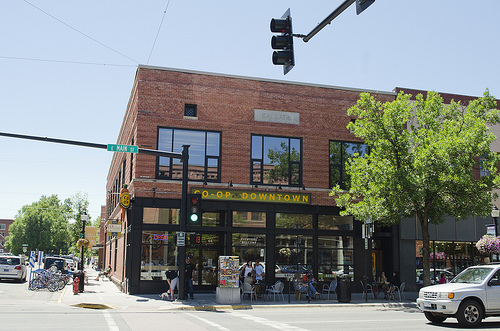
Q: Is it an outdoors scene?
A: Yes, it is outdoors.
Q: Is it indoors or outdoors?
A: It is outdoors.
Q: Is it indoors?
A: No, it is outdoors.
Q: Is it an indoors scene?
A: No, it is outdoors.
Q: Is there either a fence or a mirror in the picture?
A: No, there are no fences or mirrors.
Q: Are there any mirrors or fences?
A: No, there are no fences or mirrors.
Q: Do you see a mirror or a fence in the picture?
A: No, there are no fences or mirrors.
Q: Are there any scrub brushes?
A: No, there are no scrub brushes.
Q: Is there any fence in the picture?
A: No, there are no fences.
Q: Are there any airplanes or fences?
A: No, there are no fences or airplanes.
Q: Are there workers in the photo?
A: No, there are no workers.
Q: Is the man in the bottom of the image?
A: Yes, the man is in the bottom of the image.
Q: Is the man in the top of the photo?
A: No, the man is in the bottom of the image.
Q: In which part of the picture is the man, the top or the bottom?
A: The man is in the bottom of the image.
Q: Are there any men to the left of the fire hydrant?
A: No, the man is to the right of the fire hydrant.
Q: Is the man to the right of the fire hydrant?
A: Yes, the man is to the right of the fire hydrant.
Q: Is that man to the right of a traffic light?
A: No, the man is to the right of the fire hydrant.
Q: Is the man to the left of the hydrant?
A: No, the man is to the right of the hydrant.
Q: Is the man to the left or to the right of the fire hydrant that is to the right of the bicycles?
A: The man is to the right of the hydrant.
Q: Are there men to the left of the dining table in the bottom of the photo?
A: Yes, there is a man to the left of the dining table.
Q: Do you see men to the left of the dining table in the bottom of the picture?
A: Yes, there is a man to the left of the dining table.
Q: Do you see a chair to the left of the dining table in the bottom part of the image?
A: No, there is a man to the left of the dining table.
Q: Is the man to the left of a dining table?
A: Yes, the man is to the left of a dining table.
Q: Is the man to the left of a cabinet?
A: No, the man is to the left of a dining table.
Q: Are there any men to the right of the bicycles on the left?
A: Yes, there is a man to the right of the bicycles.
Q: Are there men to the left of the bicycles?
A: No, the man is to the right of the bicycles.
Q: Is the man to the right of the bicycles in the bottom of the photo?
A: Yes, the man is to the right of the bicycles.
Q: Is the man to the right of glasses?
A: No, the man is to the right of the bicycles.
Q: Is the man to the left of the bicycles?
A: No, the man is to the right of the bicycles.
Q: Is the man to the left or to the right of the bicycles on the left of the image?
A: The man is to the right of the bicycles.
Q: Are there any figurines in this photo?
A: No, there are no figurines.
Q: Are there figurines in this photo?
A: No, there are no figurines.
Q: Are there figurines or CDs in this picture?
A: No, there are no figurines or cds.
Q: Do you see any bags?
A: No, there are no bags.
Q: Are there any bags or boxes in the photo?
A: No, there are no bags or boxes.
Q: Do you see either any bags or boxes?
A: No, there are no bags or boxes.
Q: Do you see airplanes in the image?
A: No, there are no airplanes.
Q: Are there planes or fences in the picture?
A: No, there are no planes or fences.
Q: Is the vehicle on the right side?
A: Yes, the vehicle is on the right of the image.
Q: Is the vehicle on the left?
A: No, the vehicle is on the right of the image.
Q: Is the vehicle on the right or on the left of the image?
A: The vehicle is on the right of the image.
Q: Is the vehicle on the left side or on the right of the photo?
A: The vehicle is on the right of the image.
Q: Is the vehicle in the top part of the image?
A: No, the vehicle is in the bottom of the image.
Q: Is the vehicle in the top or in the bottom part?
A: The vehicle is in the bottom of the image.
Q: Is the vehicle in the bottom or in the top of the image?
A: The vehicle is in the bottom of the image.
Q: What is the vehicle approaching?
A: The vehicle is approaching the intersection.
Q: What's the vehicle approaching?
A: The vehicle is approaching the intersection.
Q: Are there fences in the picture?
A: No, there are no fences.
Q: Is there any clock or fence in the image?
A: No, there are no fences or clocks.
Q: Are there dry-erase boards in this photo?
A: No, there are no dry-erase boards.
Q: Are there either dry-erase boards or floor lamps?
A: No, there are no dry-erase boards or floor lamps.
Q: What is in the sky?
A: The clouds are in the sky.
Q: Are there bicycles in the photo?
A: Yes, there are bicycles.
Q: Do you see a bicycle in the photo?
A: Yes, there are bicycles.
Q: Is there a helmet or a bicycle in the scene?
A: Yes, there are bicycles.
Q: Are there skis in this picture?
A: No, there are no skis.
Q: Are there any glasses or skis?
A: No, there are no skis or glasses.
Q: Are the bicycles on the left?
A: Yes, the bicycles are on the left of the image.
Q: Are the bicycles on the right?
A: No, the bicycles are on the left of the image.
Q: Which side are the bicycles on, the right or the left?
A: The bicycles are on the left of the image.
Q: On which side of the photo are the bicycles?
A: The bicycles are on the left of the image.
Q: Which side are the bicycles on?
A: The bicycles are on the left of the image.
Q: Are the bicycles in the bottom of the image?
A: Yes, the bicycles are in the bottom of the image.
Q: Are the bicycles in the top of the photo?
A: No, the bicycles are in the bottom of the image.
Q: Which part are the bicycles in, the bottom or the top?
A: The bicycles are in the bottom of the image.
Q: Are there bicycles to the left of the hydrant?
A: Yes, there are bicycles to the left of the hydrant.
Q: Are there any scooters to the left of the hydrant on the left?
A: No, there are bicycles to the left of the hydrant.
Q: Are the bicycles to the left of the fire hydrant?
A: Yes, the bicycles are to the left of the fire hydrant.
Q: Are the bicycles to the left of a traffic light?
A: No, the bicycles are to the left of the fire hydrant.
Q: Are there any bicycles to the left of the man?
A: Yes, there are bicycles to the left of the man.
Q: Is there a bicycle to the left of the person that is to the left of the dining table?
A: Yes, there are bicycles to the left of the man.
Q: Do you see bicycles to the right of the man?
A: No, the bicycles are to the left of the man.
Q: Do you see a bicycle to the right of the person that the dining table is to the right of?
A: No, the bicycles are to the left of the man.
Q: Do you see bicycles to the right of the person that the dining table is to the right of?
A: No, the bicycles are to the left of the man.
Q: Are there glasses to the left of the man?
A: No, there are bicycles to the left of the man.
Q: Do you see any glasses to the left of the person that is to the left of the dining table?
A: No, there are bicycles to the left of the man.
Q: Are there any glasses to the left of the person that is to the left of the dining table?
A: No, there are bicycles to the left of the man.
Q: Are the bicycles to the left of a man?
A: Yes, the bicycles are to the left of a man.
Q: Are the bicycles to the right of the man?
A: No, the bicycles are to the left of the man.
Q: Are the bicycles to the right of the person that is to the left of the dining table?
A: No, the bicycles are to the left of the man.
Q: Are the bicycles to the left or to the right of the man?
A: The bicycles are to the left of the man.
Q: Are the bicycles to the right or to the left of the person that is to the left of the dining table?
A: The bicycles are to the left of the man.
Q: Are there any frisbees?
A: No, there are no frisbees.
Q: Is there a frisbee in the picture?
A: No, there are no frisbees.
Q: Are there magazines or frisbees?
A: No, there are no frisbees or magazines.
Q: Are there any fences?
A: No, there are no fences.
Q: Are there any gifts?
A: No, there are no gifts.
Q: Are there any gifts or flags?
A: No, there are no gifts or flags.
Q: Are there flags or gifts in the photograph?
A: No, there are no gifts or flags.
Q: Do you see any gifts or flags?
A: No, there are no gifts or flags.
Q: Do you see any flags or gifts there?
A: No, there are no gifts or flags.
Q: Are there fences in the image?
A: No, there are no fences.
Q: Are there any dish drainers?
A: No, there are no dish drainers.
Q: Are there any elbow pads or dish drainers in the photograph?
A: No, there are no dish drainers or elbow pads.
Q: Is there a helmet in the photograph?
A: No, there are no helmets.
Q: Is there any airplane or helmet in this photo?
A: No, there are no helmets or airplanes.